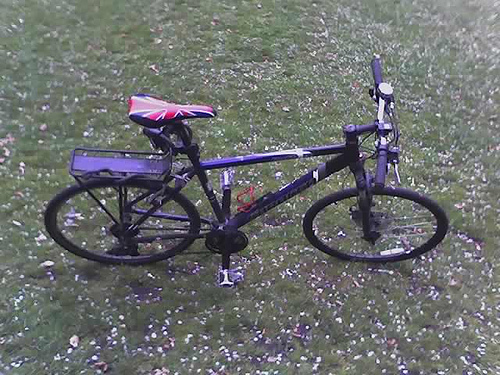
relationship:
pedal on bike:
[212, 260, 245, 300] [41, 56, 449, 267]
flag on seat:
[127, 93, 217, 123] [125, 87, 223, 173]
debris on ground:
[165, 267, 413, 369] [2, 1, 499, 372]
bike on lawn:
[41, 56, 449, 267] [0, 0, 499, 373]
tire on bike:
[303, 184, 450, 264] [41, 56, 449, 267]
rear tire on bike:
[40, 174, 204, 264] [41, 56, 449, 267]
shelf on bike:
[66, 139, 178, 183] [41, 56, 449, 267]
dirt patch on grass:
[127, 274, 163, 304] [4, 2, 499, 373]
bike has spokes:
[51, 100, 481, 327] [59, 191, 188, 260]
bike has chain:
[41, 56, 449, 267] [117, 202, 249, 267]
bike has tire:
[41, 56, 449, 267] [303, 184, 450, 264]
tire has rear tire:
[303, 184, 450, 264] [41, 177, 201, 266]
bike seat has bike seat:
[127, 90, 217, 131] [127, 92, 218, 129]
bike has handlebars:
[41, 56, 449, 267] [349, 56, 402, 187]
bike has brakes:
[41, 56, 449, 267] [372, 90, 407, 185]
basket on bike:
[72, 144, 174, 237] [41, 56, 449, 267]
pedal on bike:
[219, 167, 234, 187] [41, 56, 449, 267]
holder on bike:
[230, 182, 260, 211] [41, 56, 449, 267]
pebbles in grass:
[49, 310, 125, 374] [21, 276, 210, 372]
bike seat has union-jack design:
[127, 92, 218, 129] [134, 95, 212, 117]